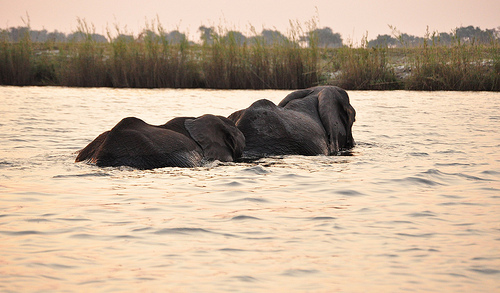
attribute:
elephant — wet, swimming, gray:
[75, 114, 246, 170]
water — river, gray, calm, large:
[0, 86, 499, 293]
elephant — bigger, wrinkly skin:
[227, 85, 356, 156]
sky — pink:
[0, 0, 499, 50]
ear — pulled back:
[184, 114, 236, 162]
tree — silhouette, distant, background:
[199, 27, 215, 46]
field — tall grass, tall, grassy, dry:
[0, 43, 499, 91]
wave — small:
[334, 189, 364, 196]